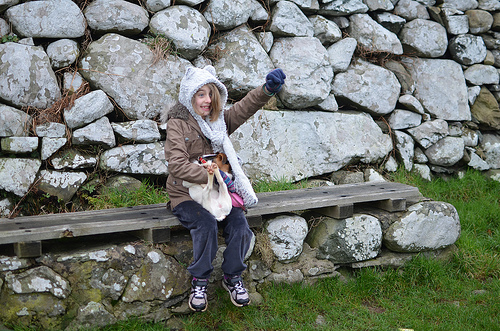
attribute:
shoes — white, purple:
[183, 273, 273, 314]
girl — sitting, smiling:
[159, 56, 251, 301]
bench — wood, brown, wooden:
[12, 185, 416, 215]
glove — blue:
[267, 67, 293, 99]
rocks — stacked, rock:
[17, 29, 426, 106]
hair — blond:
[202, 87, 225, 122]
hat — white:
[180, 63, 236, 134]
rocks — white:
[20, 207, 476, 255]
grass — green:
[275, 231, 492, 320]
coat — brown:
[161, 98, 244, 218]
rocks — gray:
[411, 28, 500, 109]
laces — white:
[192, 282, 214, 309]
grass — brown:
[49, 60, 117, 180]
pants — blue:
[171, 201, 254, 304]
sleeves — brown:
[171, 129, 215, 195]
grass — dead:
[148, 37, 182, 54]